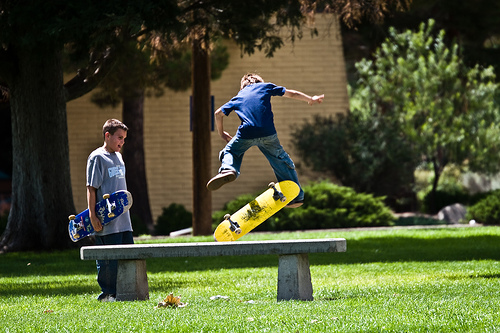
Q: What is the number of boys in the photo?
A: Two.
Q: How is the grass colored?
A: Green.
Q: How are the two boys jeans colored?
A: Blue.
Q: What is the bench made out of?
A: Concrete.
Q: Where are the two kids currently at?
A: A park.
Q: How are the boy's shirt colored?
A: Gray and blue.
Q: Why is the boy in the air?
A: He's doing a trick.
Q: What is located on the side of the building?
A: A tree.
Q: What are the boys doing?
A: Skating.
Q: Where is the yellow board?
A: In the air.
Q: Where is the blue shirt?
A: On the right boy.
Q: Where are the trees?
A: In front of the building.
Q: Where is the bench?
A: Below the boys.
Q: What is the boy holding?
A: A skateboard.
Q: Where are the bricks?
A: On the building.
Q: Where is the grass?
A: On the lawn.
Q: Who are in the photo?
A: Two boys.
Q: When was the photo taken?
A: Sunny day.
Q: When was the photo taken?
A: During skating.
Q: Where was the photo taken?
A: In a field.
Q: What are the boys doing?
A: Skating.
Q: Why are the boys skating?
A: For fun.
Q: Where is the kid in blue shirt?
A: In air.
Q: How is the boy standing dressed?
A: In gray shirt and pants.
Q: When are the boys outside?
A: Daytime.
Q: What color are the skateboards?
A: Yellow and Blue.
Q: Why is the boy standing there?
A: Watching.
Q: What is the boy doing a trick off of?
A: A bench.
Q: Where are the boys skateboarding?
A: The park.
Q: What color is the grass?
A: Green.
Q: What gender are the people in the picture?
A: Male.